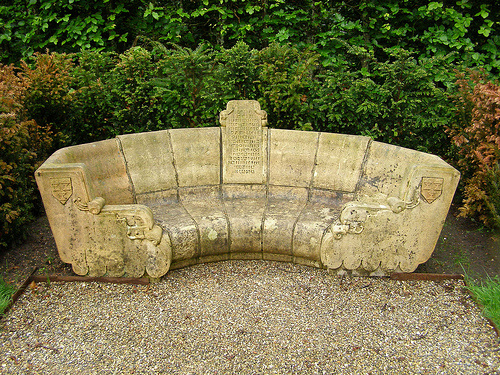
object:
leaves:
[347, 77, 388, 106]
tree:
[0, 47, 74, 149]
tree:
[348, 42, 467, 139]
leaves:
[418, 100, 454, 129]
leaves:
[478, 17, 499, 36]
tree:
[308, 47, 391, 144]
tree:
[390, 61, 456, 132]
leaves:
[267, 70, 322, 110]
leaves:
[346, 105, 381, 126]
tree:
[251, 46, 320, 131]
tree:
[163, 51, 251, 128]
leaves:
[168, 49, 217, 98]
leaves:
[428, 25, 476, 50]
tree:
[387, 4, 487, 75]